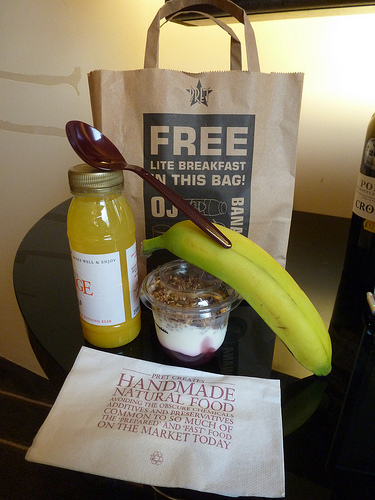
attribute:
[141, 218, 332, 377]
banana — ripe, whole, yellow, unripe, green, large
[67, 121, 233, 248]
spoon — plastic, brown, shiny, black, red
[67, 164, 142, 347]
bottle — unopened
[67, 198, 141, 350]
orange juice — yellow, liquid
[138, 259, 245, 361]
parfait — yogurt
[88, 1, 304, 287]
bag — brown, paper, large, black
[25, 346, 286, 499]
napkin — white, large, paper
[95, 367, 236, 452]
print — red, black, bold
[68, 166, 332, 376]
breakfast — free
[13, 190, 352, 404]
table — black, round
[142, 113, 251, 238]
print — black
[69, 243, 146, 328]
label — white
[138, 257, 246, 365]
cup — plastic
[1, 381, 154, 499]
floor — black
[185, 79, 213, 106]
star — black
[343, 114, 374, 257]
bottle — wine bottle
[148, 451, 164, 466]
symbol — recycling symbol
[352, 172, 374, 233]
label — gold